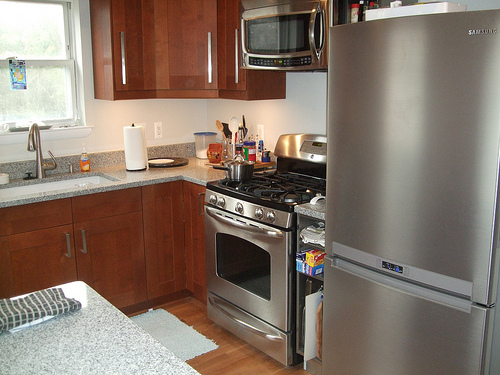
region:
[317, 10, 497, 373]
stainless steel refrigerator in kitchen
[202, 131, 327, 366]
stainless steel stove in kitchen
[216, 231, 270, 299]
window in oven door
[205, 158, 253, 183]
pot sitting on burner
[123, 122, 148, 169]
roll of paper towels on counter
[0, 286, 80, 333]
kitchen towel on counter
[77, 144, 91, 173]
bottle of hand soap on sink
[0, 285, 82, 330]
Black and white checkered towel on the counter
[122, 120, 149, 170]
Roll of paper towels on the counter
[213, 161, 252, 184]
Silver pot on the stove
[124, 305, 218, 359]
Throw rug on the floor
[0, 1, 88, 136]
Window over the sink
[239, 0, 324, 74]
Microwave oven above the stove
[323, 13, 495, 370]
Silver refrigerator to the right of the stove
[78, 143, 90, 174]
Liquid handsoap at the sink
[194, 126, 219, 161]
White substance in plastic container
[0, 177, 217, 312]
Wooden cabinets under the sink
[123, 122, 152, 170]
a white paper towel roll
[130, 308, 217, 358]
part of a white rug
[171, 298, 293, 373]
part of a hardwood floor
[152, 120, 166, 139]
a white wall outlet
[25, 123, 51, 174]
a gray sink faucet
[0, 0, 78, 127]
part of a kitchen window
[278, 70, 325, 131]
part of a white wall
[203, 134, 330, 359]
part of an oven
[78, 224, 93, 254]
a gray cabinet handle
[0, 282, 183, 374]
part of a kitchen counter top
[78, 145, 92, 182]
Liquid hand soap at the sink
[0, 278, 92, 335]
Two folded towels on the counter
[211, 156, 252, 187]
Silver pot on the stove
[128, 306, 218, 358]
Throw rug on the floor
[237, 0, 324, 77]
Microwave oven over the stove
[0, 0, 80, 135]
Window over the sink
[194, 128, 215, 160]
Plastic canister on the counter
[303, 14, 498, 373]
Silver refrigerator to the right of the stove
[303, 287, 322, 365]
Large white plastic cutting board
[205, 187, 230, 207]
knobs on a stove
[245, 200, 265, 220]
knob on a stove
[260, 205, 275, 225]
knob on a stove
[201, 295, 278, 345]
handle on a stove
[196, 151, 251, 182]
pot on a stove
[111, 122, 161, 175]
paper towel on a counter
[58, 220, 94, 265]
handle on a cabinet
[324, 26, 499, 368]
refrigerator in a kitchen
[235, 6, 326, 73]
an over the range microwave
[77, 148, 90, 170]
a soap pump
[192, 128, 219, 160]
a blue and white plastic container